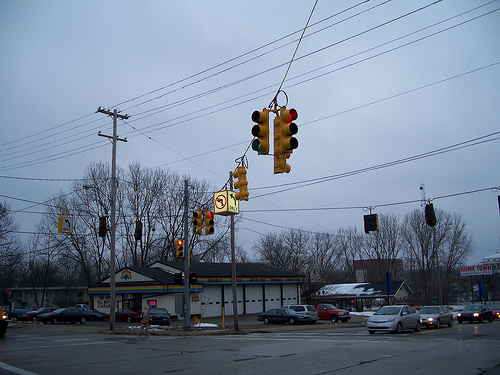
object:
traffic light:
[274, 104, 299, 158]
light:
[250, 138, 267, 155]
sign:
[214, 191, 225, 214]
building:
[92, 260, 306, 318]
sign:
[147, 299, 157, 307]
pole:
[95, 106, 131, 333]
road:
[0, 318, 499, 375]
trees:
[0, 209, 24, 304]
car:
[365, 303, 423, 335]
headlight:
[427, 316, 434, 324]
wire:
[0, 0, 366, 148]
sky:
[1, 0, 498, 281]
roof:
[305, 280, 413, 300]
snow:
[314, 282, 382, 296]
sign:
[227, 189, 239, 214]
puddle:
[103, 335, 139, 347]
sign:
[458, 262, 494, 279]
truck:
[313, 301, 351, 324]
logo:
[118, 267, 131, 284]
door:
[120, 293, 142, 316]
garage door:
[199, 282, 224, 319]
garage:
[192, 277, 303, 319]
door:
[224, 282, 247, 317]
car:
[416, 305, 454, 330]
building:
[300, 278, 413, 311]